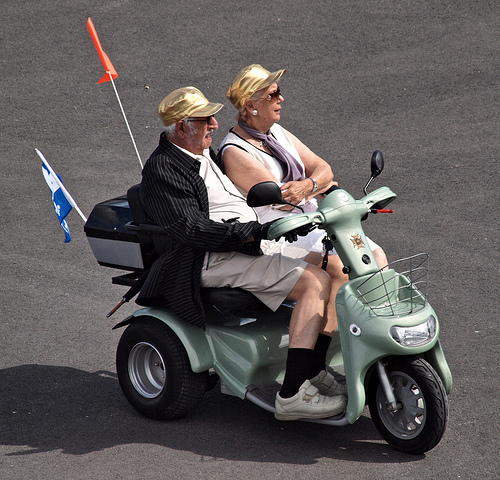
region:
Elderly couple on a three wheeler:
[90, 60, 452, 454]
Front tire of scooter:
[374, 353, 448, 455]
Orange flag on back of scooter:
[87, 15, 116, 85]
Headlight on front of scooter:
[390, 318, 437, 350]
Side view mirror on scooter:
[247, 180, 287, 206]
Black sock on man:
[284, 340, 316, 405]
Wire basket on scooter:
[363, 255, 433, 312]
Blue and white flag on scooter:
[38, 165, 76, 242]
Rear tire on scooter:
[114, 318, 196, 422]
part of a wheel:
[402, 398, 426, 422]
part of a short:
[303, 400, 318, 434]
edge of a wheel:
[411, 385, 424, 405]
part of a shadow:
[298, 427, 303, 435]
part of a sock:
[291, 386, 296, 426]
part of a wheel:
[398, 371, 406, 380]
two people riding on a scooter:
[84, 67, 474, 451]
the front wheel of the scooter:
[368, 352, 452, 458]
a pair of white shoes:
[272, 372, 352, 421]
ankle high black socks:
[284, 332, 328, 393]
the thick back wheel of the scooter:
[110, 320, 199, 422]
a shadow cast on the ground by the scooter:
[3, 357, 422, 469]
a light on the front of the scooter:
[388, 322, 440, 347]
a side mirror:
[242, 180, 289, 205]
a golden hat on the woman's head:
[223, 68, 285, 98]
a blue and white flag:
[32, 150, 72, 240]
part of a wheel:
[425, 427, 426, 428]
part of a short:
[251, 240, 258, 252]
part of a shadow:
[135, 363, 152, 428]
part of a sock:
[286, 374, 302, 397]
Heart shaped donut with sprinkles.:
[65, 334, 79, 345]